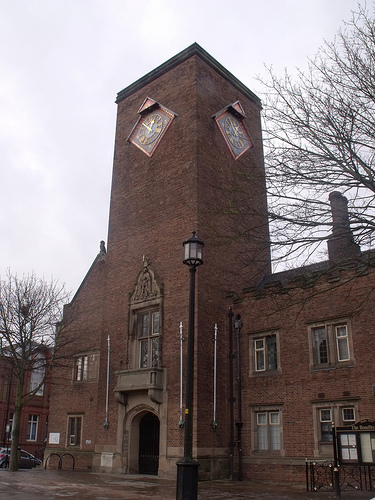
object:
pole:
[174, 268, 203, 498]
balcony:
[110, 366, 162, 393]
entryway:
[118, 401, 167, 475]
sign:
[334, 426, 373, 464]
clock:
[125, 97, 178, 158]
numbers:
[155, 126, 161, 134]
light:
[182, 230, 204, 267]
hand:
[145, 117, 157, 133]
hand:
[139, 119, 151, 130]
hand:
[228, 117, 238, 136]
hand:
[231, 124, 238, 136]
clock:
[209, 97, 255, 159]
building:
[41, 40, 375, 490]